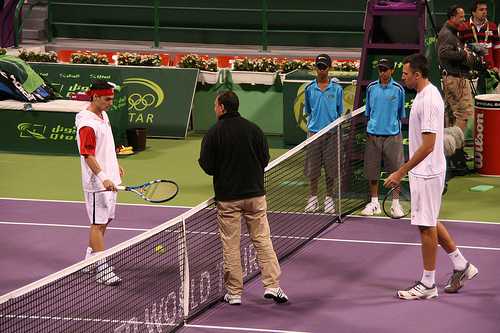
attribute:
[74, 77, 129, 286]
man — red, white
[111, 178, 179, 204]
tennis racket — blue, black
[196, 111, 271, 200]
jacket — grey, black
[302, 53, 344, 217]
man — young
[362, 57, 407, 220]
man — young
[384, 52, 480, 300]
player — all white, wearing all white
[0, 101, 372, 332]
net — stretched, tennis, tennis court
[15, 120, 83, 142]
logo — sponsor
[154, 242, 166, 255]
ball — yellow, green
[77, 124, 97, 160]
sleeve — red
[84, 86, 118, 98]
headband — red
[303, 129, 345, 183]
shorts — brown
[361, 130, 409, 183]
shorts — brown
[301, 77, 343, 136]
shirt — blue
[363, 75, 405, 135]
shirt — blue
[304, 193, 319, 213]
shoe — white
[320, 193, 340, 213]
shoe — white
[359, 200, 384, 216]
shoe — white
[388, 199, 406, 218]
shoe — white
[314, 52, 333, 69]
cap — black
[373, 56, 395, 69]
cap — black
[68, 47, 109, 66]
flowers — white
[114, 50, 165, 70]
flowers — white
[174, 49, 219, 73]
flowers — white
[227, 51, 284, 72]
flowers — around, white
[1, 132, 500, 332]
tennis court — blue, purple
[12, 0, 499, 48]
railing — metal, green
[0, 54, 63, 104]
bag — black, green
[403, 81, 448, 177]
shirt — white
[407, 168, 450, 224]
shorts — white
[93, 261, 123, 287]
shoe — white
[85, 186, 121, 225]
shorts — white, black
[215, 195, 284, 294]
pants — khaki, tan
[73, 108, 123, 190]
vest — white